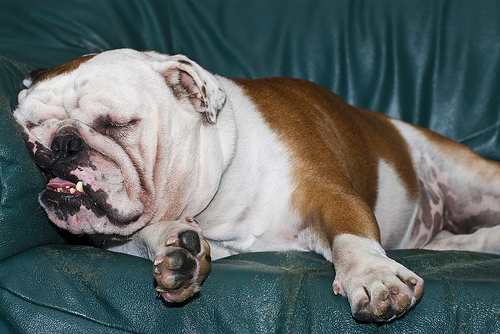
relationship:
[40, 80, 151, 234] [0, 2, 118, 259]
dog face laying on couch arm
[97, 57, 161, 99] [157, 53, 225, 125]
hair with spots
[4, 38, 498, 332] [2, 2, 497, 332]
dog sleeping on couch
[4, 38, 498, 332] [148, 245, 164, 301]
dog has toe nails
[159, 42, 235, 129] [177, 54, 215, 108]
ear has spots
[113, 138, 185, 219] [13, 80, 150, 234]
wrinkles in dog face